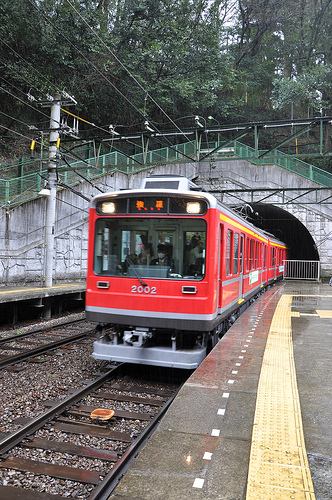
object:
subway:
[85, 174, 291, 371]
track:
[0, 318, 190, 499]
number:
[131, 283, 156, 297]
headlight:
[180, 283, 199, 295]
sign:
[132, 199, 169, 210]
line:
[243, 254, 316, 415]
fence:
[265, 258, 321, 285]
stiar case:
[16, 111, 123, 206]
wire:
[61, 27, 207, 164]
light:
[99, 198, 117, 215]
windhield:
[92, 196, 207, 283]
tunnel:
[232, 200, 321, 280]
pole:
[45, 71, 62, 290]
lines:
[181, 345, 264, 488]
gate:
[229, 204, 321, 287]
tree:
[0, 1, 332, 177]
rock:
[24, 373, 39, 388]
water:
[291, 341, 330, 391]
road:
[107, 278, 332, 499]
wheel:
[203, 319, 226, 356]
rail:
[0, 357, 184, 499]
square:
[209, 428, 219, 438]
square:
[89, 406, 114, 422]